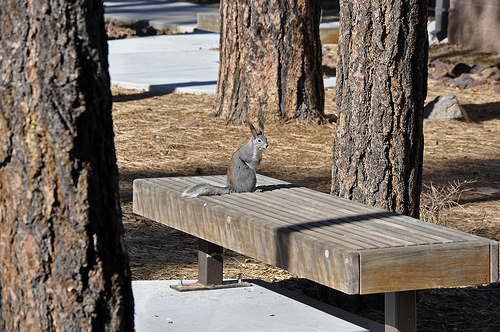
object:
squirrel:
[180, 118, 269, 199]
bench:
[130, 173, 499, 332]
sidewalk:
[130, 278, 393, 332]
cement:
[132, 278, 403, 332]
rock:
[422, 91, 471, 123]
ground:
[110, 86, 500, 332]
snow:
[318, 20, 339, 30]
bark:
[46, 97, 79, 139]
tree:
[0, 0, 137, 332]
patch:
[149, 108, 184, 124]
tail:
[179, 182, 228, 199]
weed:
[419, 177, 479, 223]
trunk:
[329, 0, 431, 219]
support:
[383, 290, 419, 325]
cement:
[108, 32, 224, 95]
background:
[102, 1, 438, 93]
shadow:
[252, 183, 307, 193]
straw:
[444, 146, 463, 155]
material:
[437, 135, 474, 161]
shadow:
[425, 158, 500, 179]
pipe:
[430, 0, 450, 45]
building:
[445, 2, 500, 54]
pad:
[169, 279, 251, 292]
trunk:
[0, 0, 138, 332]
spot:
[227, 158, 235, 185]